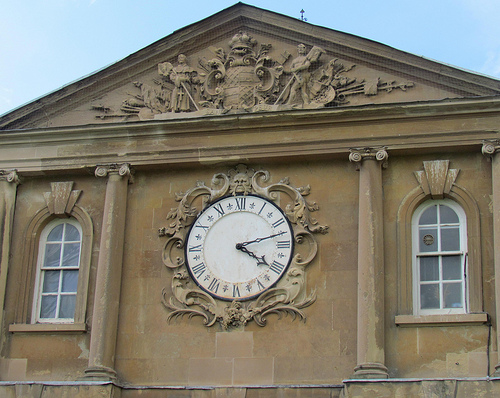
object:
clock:
[180, 191, 300, 301]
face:
[188, 192, 292, 302]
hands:
[236, 230, 289, 246]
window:
[418, 282, 443, 312]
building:
[0, 1, 500, 396]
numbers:
[211, 202, 228, 218]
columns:
[355, 157, 393, 378]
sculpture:
[92, 26, 417, 124]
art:
[158, 166, 328, 333]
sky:
[0, 2, 499, 116]